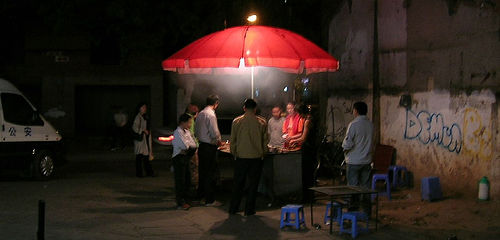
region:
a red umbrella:
[159, 22, 339, 79]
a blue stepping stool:
[276, 202, 309, 233]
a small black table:
[305, 182, 379, 234]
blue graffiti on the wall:
[403, 103, 465, 158]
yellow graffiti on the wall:
[460, 101, 496, 163]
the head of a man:
[350, 96, 371, 117]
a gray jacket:
[337, 115, 376, 166]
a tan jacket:
[228, 113, 270, 161]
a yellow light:
[246, 10, 258, 25]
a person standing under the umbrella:
[228, 94, 270, 216]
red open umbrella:
[152, 11, 344, 90]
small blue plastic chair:
[279, 196, 304, 231]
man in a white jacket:
[337, 96, 383, 190]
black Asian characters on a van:
[5, 120, 36, 141]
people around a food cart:
[162, 10, 344, 207]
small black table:
[311, 178, 372, 226]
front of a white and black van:
[0, 67, 88, 185]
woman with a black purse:
[129, 86, 160, 189]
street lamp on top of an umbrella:
[239, 7, 264, 35]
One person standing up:
[338, 94, 390, 208]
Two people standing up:
[266, 99, 308, 155]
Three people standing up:
[228, 96, 320, 218]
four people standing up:
[236, 93, 377, 217]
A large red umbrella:
[145, 15, 347, 88]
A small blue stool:
[269, 204, 311, 237]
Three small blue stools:
[271, 199, 380, 236]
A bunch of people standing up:
[105, 92, 404, 192]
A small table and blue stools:
[297, 177, 378, 225]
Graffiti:
[389, 99, 471, 162]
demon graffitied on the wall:
[380, 102, 489, 157]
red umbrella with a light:
[136, 10, 350, 98]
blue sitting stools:
[266, 180, 370, 237]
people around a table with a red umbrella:
[106, 21, 416, 205]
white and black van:
[1, 66, 83, 190]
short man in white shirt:
[163, 106, 224, 216]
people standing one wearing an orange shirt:
[256, 79, 343, 200]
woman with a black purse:
[115, 85, 172, 185]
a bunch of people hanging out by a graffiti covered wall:
[118, 30, 497, 218]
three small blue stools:
[281, 192, 374, 233]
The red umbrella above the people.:
[159, 12, 341, 84]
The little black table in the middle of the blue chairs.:
[304, 180, 385, 228]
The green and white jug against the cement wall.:
[475, 175, 495, 203]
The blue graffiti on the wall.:
[398, 100, 465, 161]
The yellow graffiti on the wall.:
[458, 100, 496, 162]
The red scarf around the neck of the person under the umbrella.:
[283, 112, 303, 137]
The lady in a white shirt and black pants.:
[171, 111, 199, 213]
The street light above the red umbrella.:
[241, 11, 261, 25]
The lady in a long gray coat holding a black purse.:
[127, 96, 156, 178]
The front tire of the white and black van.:
[35, 149, 57, 178]